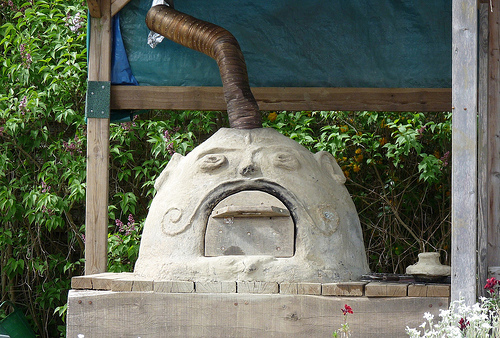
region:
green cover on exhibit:
[124, 9, 438, 89]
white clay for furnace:
[169, 130, 368, 298]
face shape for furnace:
[179, 143, 411, 298]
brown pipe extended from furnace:
[135, 4, 297, 159]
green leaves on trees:
[19, 29, 91, 255]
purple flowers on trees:
[15, 21, 75, 144]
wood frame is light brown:
[77, 20, 119, 314]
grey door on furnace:
[193, 187, 285, 254]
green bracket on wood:
[76, 68, 122, 135]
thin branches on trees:
[365, 162, 430, 266]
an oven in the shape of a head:
[130, 62, 371, 282]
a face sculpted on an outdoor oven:
[135, 129, 367, 281]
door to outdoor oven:
[202, 185, 299, 259]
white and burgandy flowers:
[406, 272, 496, 336]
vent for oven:
[137, 6, 261, 131]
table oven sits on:
[63, 275, 460, 337]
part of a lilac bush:
[5, 90, 77, 246]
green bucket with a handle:
[1, 292, 39, 337]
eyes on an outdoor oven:
[192, 141, 314, 182]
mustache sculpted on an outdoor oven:
[152, 173, 352, 243]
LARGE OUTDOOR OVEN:
[90, 65, 444, 331]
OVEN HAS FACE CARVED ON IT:
[127, 105, 391, 288]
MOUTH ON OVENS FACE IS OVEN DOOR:
[186, 178, 325, 282]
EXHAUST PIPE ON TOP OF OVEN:
[117, 1, 298, 150]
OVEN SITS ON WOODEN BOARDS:
[74, 215, 463, 331]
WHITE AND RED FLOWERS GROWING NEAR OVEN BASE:
[315, 282, 495, 336]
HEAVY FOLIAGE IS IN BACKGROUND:
[2, 40, 88, 323]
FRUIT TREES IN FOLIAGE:
[258, 109, 453, 210]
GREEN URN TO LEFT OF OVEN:
[1, 277, 47, 336]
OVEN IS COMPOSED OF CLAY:
[117, 112, 403, 300]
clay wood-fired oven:
[106, 95, 383, 281]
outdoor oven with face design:
[112, 106, 407, 317]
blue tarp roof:
[100, 0, 475, 100]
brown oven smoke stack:
[140, 0, 270, 130]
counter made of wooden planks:
[60, 267, 470, 317]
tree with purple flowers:
[0, 2, 80, 319]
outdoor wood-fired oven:
[100, 110, 386, 300]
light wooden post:
[80, 10, 115, 277]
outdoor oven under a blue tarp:
[100, 7, 439, 299]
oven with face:
[126, 120, 393, 296]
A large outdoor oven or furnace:
[126, 110, 373, 275]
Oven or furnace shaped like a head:
[135, 130, 350, 270]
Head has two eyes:
[190, 140, 305, 180]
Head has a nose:
[230, 145, 260, 175]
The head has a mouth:
[190, 180, 305, 280]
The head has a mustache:
[155, 175, 340, 241]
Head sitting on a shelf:
[78, 130, 458, 307]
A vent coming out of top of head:
[145, 5, 265, 145]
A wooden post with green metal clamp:
[67, 20, 120, 270]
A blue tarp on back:
[109, 16, 498, 106]